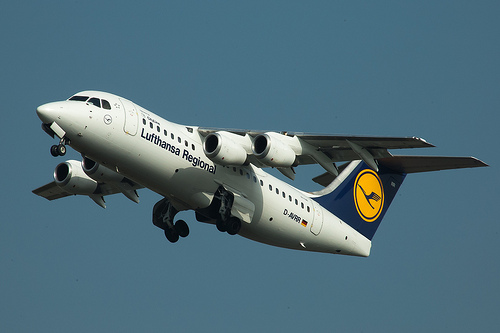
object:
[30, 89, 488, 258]
plane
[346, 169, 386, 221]
flag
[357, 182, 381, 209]
picture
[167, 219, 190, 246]
wheel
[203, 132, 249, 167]
engine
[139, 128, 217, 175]
writing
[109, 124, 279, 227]
body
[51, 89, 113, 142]
cock pit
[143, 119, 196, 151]
window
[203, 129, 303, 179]
jet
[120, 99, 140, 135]
door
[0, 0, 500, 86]
sky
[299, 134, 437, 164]
wing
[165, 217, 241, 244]
gear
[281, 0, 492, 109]
air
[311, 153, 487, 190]
tail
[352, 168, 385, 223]
logo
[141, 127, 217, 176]
letter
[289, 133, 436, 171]
flap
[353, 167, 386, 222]
symbol